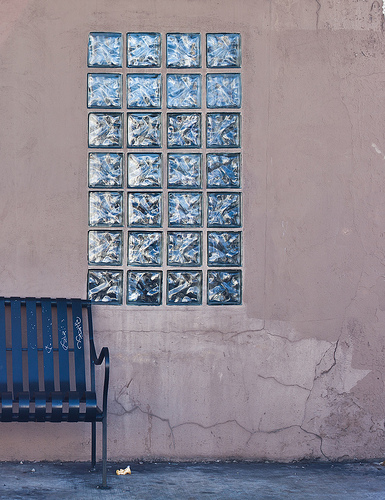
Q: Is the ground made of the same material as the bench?
A: No, the ground is made of concrete and the bench is made of metal.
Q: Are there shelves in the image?
A: No, there are no shelves.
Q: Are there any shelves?
A: No, there are no shelves.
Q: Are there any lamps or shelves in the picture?
A: No, there are no shelves or lamps.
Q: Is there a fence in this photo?
A: No, there are no fences.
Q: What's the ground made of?
A: The ground is made of concrete.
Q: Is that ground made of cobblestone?
A: No, the ground is made of cement.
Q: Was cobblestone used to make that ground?
A: No, the ground is made of cement.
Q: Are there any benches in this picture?
A: Yes, there is a bench.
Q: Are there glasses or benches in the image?
A: Yes, there is a bench.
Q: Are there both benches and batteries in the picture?
A: No, there is a bench but no batteries.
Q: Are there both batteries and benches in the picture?
A: No, there is a bench but no batteries.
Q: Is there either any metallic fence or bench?
A: Yes, there is a metal bench.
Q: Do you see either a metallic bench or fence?
A: Yes, there is a metal bench.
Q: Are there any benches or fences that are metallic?
A: Yes, the bench is metallic.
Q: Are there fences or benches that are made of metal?
A: Yes, the bench is made of metal.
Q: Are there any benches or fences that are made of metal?
A: Yes, the bench is made of metal.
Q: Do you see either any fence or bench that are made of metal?
A: Yes, the bench is made of metal.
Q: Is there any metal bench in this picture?
A: Yes, there is a metal bench.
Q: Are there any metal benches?
A: Yes, there is a metal bench.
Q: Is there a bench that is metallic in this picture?
A: Yes, there is a metal bench.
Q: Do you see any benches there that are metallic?
A: Yes, there is a bench that is metallic.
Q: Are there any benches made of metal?
A: Yes, there is a bench that is made of metal.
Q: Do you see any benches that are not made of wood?
A: Yes, there is a bench that is made of metal.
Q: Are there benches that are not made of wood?
A: Yes, there is a bench that is made of metal.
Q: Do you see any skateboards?
A: No, there are no skateboards.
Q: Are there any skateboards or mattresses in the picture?
A: No, there are no skateboards or mattresses.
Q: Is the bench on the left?
A: Yes, the bench is on the left of the image.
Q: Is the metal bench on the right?
A: No, the bench is on the left of the image.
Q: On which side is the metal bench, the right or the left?
A: The bench is on the left of the image.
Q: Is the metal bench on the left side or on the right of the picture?
A: The bench is on the left of the image.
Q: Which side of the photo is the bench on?
A: The bench is on the left of the image.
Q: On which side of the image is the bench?
A: The bench is on the left of the image.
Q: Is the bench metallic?
A: Yes, the bench is metallic.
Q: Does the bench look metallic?
A: Yes, the bench is metallic.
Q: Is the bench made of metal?
A: Yes, the bench is made of metal.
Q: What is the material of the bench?
A: The bench is made of metal.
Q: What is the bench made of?
A: The bench is made of metal.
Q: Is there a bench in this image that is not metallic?
A: No, there is a bench but it is metallic.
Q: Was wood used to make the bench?
A: No, the bench is made of metal.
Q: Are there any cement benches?
A: No, there is a bench but it is made of metal.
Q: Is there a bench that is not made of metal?
A: No, there is a bench but it is made of metal.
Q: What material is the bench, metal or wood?
A: The bench is made of metal.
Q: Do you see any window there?
A: Yes, there is a window.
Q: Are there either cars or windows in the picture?
A: Yes, there is a window.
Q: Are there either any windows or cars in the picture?
A: Yes, there is a window.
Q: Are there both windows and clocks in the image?
A: No, there is a window but no clocks.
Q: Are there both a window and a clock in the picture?
A: No, there is a window but no clocks.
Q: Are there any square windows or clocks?
A: Yes, there is a square window.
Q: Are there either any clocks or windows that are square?
A: Yes, the window is square.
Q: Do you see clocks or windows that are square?
A: Yes, the window is square.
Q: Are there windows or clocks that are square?
A: Yes, the window is square.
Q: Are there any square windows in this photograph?
A: Yes, there is a square window.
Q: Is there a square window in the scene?
A: Yes, there is a square window.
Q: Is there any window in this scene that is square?
A: Yes, there is a window that is square.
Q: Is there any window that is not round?
A: Yes, there is a square window.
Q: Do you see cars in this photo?
A: No, there are no cars.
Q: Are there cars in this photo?
A: No, there are no cars.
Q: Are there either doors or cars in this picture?
A: No, there are no cars or doors.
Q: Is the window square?
A: Yes, the window is square.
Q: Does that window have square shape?
A: Yes, the window is square.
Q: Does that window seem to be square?
A: Yes, the window is square.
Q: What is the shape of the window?
A: The window is square.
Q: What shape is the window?
A: The window is square.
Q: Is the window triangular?
A: No, the window is square.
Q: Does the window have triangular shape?
A: No, the window is square.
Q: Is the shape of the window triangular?
A: No, the window is square.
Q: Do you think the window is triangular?
A: No, the window is square.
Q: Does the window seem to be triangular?
A: No, the window is square.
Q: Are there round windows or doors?
A: No, there is a window but it is square.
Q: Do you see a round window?
A: No, there is a window but it is square.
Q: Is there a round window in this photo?
A: No, there is a window but it is square.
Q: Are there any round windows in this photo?
A: No, there is a window but it is square.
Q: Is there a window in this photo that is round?
A: No, there is a window but it is square.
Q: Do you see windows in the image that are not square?
A: No, there is a window but it is square.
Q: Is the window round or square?
A: The window is square.